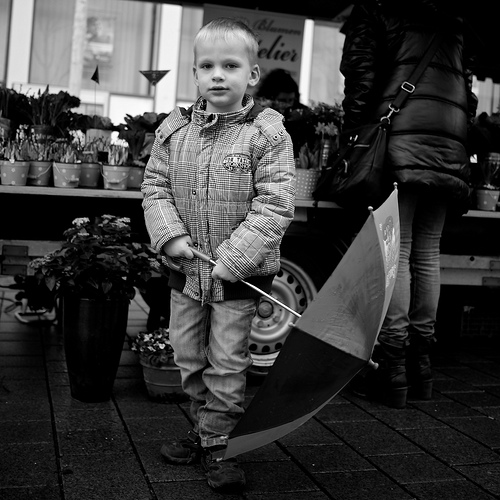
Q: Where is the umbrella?
A: Boy's hand.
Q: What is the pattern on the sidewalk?
A: Rectangles.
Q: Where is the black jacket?
A: On adult.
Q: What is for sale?
A: Plants.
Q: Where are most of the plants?
A: On table.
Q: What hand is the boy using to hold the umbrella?
A: Both.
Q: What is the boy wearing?
A: Puffy coat.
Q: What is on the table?
A: Flower pots.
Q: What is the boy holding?
A: An umbrella.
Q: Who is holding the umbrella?
A: A young boy.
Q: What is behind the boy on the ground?
A: A tire.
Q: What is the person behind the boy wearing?
A: Puffy coat.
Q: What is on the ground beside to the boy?
A: A plant.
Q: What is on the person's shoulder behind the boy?
A: A purse.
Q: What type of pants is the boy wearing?
A: Jeans.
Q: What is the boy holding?
A: An umbrella.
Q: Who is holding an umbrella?
A: The boy.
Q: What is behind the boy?
A: A plant stand.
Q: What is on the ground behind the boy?
A: Potted plants.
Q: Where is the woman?
A: To the right of the boy.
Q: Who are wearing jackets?
A: The woman and the boy.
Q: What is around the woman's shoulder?
A: A handbag.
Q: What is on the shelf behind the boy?
A: Plants.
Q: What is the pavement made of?
A: Tiles.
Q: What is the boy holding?
A: An umbrella.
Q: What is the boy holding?
A: Umbrella.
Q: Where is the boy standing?
A: Near flowers.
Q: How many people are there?
A: Two.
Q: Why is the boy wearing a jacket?
A: Chilly.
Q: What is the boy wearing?
A: Jacket.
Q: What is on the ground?
A: Flower.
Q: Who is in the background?
A: Lady.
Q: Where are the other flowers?
A: Table.